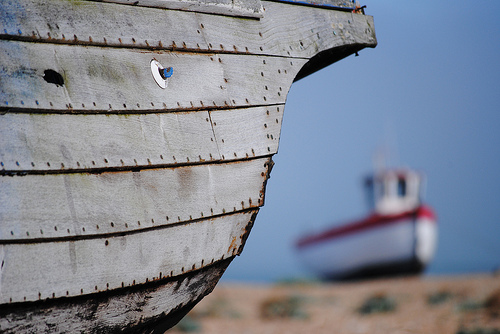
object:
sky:
[220, 1, 499, 283]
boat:
[0, 0, 377, 332]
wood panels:
[208, 104, 287, 161]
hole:
[43, 68, 65, 88]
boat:
[284, 160, 446, 282]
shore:
[158, 271, 499, 333]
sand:
[167, 270, 499, 333]